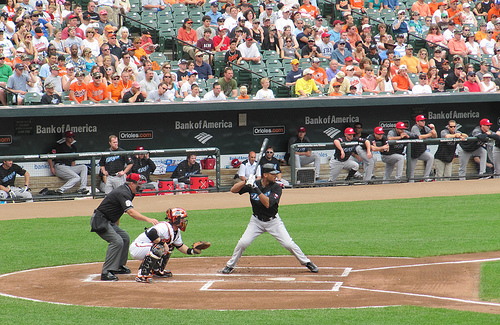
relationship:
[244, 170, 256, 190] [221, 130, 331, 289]
white glove on player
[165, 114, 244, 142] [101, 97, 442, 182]
letters in dugout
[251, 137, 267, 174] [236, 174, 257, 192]
bat in hand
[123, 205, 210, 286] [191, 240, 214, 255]
catcher holding glove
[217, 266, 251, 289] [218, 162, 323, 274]
foot on batter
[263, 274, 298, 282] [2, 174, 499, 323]
base on field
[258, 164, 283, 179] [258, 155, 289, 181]
helmet on man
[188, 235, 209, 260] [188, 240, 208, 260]
glove on hand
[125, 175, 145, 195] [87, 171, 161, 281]
mask on umpire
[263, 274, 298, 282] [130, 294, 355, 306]
base in dirt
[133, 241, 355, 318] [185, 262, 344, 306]
lines in dirt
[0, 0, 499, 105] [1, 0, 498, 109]
crowd in stands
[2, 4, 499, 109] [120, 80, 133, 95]
people in shirt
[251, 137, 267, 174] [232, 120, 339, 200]
bat holding bat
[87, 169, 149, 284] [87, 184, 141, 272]
man in uniform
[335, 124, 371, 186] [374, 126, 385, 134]
man in ball cap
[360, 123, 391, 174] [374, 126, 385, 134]
man in ball cap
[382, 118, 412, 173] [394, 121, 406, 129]
man in ball cap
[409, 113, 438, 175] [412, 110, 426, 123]
man in ball cap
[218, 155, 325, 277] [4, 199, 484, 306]
batter in field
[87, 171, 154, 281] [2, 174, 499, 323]
umpire in field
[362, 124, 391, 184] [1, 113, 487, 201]
man in dugout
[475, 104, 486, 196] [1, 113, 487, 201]
player in dugout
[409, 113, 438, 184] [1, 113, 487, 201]
man in dugout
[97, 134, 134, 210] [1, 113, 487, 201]
player in dugout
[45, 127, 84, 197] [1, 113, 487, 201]
player in dugout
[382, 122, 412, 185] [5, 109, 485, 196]
man in dugout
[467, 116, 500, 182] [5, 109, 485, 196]
player in dugout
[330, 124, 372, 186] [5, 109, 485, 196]
man in dugout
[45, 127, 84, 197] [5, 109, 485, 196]
player in dugout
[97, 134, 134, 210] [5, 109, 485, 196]
player in dugout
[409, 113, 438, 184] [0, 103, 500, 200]
man in dugout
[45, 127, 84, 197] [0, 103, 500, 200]
player in dugout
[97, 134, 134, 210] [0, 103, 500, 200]
player in dugout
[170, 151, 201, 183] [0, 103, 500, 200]
player in dugout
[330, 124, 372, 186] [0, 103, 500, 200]
man in dugout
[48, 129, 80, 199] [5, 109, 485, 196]
player in dugout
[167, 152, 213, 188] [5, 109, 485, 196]
player in dugout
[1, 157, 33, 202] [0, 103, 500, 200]
player in dugout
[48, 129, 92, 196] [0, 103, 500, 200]
player in dugout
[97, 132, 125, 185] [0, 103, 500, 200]
player in dugout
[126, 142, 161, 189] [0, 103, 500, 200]
player in dugout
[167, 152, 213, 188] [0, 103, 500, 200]
player in dugout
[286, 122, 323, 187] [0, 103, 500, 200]
player in dugout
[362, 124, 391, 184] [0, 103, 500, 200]
man in dugout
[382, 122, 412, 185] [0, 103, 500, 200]
man in dugout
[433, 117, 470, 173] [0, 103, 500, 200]
player in dugout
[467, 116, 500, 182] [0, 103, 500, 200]
player in dugout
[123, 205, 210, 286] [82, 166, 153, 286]
catcher in front of umpire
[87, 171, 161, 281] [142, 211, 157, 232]
umpire has hand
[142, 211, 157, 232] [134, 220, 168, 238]
hand on back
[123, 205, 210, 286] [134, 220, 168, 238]
catcher has back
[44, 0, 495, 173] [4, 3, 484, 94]
people in stands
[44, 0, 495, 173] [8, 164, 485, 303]
people watching game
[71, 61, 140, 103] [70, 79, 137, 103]
men wearing shirts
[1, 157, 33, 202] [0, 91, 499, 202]
player sitting in dugout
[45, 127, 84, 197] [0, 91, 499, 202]
player sitting in dugout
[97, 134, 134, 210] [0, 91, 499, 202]
player sitting in dugout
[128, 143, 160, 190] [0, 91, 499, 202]
player sitting in dugout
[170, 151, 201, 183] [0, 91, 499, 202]
player sitting in dugout